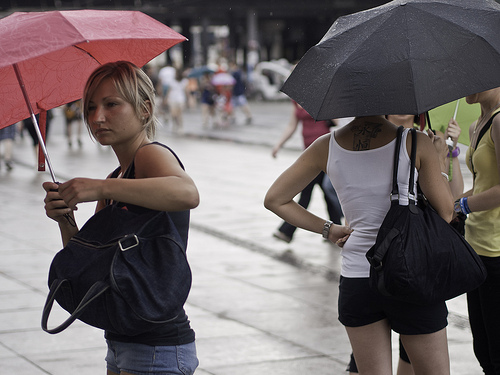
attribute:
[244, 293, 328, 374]
line — Small 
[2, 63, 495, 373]
sidewalk — concrete 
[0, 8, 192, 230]
umbrella — red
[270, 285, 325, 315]
line — Small 